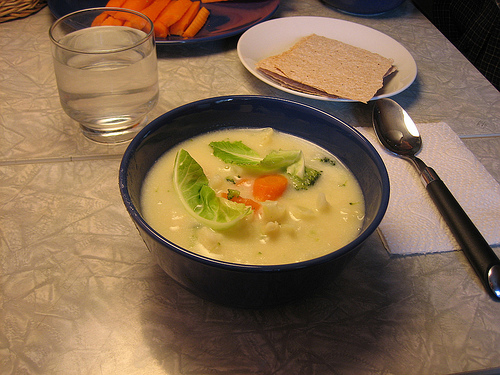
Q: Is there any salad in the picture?
A: No, there is no salad.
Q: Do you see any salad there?
A: No, there is no salad.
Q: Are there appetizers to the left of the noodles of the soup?
A: Yes, there is an appetizer to the left of the noodles.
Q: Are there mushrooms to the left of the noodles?
A: No, there is an appetizer to the left of the noodles.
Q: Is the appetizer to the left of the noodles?
A: Yes, the appetizer is to the left of the noodles.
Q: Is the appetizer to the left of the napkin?
A: Yes, the appetizer is to the left of the napkin.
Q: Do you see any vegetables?
A: Yes, there are vegetables.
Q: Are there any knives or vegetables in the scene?
A: Yes, there are vegetables.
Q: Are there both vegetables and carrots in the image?
A: Yes, there are both vegetables and a carrot.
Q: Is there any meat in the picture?
A: No, there is no meat.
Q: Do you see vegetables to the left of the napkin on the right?
A: Yes, there are vegetables to the left of the napkin.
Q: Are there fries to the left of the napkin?
A: No, there are vegetables to the left of the napkin.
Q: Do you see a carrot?
A: Yes, there are carrots.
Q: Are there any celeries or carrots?
A: Yes, there are carrots.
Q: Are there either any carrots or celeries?
A: Yes, there are carrots.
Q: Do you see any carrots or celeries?
A: Yes, there are carrots.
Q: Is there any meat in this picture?
A: No, there is no meat.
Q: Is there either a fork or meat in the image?
A: No, there are no meat or forks.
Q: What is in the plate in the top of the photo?
A: The carrots are in the plate.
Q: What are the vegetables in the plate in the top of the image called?
A: The vegetables are carrots.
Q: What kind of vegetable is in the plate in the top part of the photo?
A: The vegetables are carrots.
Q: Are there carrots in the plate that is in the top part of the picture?
A: Yes, there are carrots in the plate.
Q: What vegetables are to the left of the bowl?
A: The vegetables are carrots.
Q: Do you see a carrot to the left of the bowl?
A: Yes, there are carrots to the left of the bowl.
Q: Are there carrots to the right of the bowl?
A: No, the carrots are to the left of the bowl.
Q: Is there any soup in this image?
A: Yes, there is soup.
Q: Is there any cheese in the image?
A: No, there is no cheese.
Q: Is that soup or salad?
A: That is soup.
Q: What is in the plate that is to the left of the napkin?
A: The soup is in the plate.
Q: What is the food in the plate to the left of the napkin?
A: The food is soup.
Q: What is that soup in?
A: The soup is in the plate.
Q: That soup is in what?
A: The soup is in the plate.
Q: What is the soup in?
A: The soup is in the plate.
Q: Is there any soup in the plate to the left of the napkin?
A: Yes, there is soup in the plate.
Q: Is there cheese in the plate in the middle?
A: No, there is soup in the plate.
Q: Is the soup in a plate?
A: Yes, the soup is in a plate.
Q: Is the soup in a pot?
A: No, the soup is in a plate.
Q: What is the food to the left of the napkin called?
A: The food is soup.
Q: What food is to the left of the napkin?
A: The food is soup.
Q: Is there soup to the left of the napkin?
A: Yes, there is soup to the left of the napkin.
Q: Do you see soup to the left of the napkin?
A: Yes, there is soup to the left of the napkin.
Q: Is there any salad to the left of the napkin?
A: No, there is soup to the left of the napkin.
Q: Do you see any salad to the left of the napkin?
A: No, there is soup to the left of the napkin.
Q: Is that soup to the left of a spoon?
A: No, the soup is to the left of the napkin.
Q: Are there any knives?
A: No, there are no knives.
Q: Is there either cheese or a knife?
A: No, there are no knives or cheese.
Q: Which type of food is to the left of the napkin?
A: The food is noodles.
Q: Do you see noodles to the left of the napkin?
A: Yes, there are noodles to the left of the napkin.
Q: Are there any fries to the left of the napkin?
A: No, there are noodles to the left of the napkin.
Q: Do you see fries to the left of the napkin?
A: No, there are noodles to the left of the napkin.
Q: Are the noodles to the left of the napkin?
A: Yes, the noodles are to the left of the napkin.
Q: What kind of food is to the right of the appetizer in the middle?
A: The food is noodles.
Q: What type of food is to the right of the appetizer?
A: The food is noodles.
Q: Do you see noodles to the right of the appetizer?
A: Yes, there are noodles to the right of the appetizer.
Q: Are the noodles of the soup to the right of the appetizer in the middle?
A: Yes, the noodles are to the right of the appetizer.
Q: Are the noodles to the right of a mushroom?
A: No, the noodles are to the right of the appetizer.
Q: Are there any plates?
A: Yes, there is a plate.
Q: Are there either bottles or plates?
A: Yes, there is a plate.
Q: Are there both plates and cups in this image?
A: Yes, there are both a plate and a cup.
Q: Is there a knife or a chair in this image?
A: No, there are no knives or chairs.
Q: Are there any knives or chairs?
A: No, there are no knives or chairs.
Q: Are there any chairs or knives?
A: No, there are no knives or chairs.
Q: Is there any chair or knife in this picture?
A: No, there are no knives or chairs.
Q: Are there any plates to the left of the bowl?
A: Yes, there is a plate to the left of the bowl.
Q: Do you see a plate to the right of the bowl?
A: No, the plate is to the left of the bowl.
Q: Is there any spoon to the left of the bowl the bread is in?
A: No, there is a plate to the left of the bowl.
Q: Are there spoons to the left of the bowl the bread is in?
A: No, there is a plate to the left of the bowl.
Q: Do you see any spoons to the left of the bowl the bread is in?
A: No, there is a plate to the left of the bowl.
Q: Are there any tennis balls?
A: No, there are no tennis balls.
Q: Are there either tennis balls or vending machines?
A: No, there are no tennis balls or vending machines.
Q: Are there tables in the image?
A: Yes, there is a table.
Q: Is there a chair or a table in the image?
A: Yes, there is a table.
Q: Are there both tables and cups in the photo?
A: Yes, there are both a table and a cup.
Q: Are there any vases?
A: No, there are no vases.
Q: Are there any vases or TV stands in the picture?
A: No, there are no vases or TV stands.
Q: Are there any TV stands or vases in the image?
A: No, there are no vases or TV stands.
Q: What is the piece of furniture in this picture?
A: The piece of furniture is a table.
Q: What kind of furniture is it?
A: The piece of furniture is a table.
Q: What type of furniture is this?
A: This is a table.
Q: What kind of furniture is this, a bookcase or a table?
A: This is a table.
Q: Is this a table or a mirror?
A: This is a table.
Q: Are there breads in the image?
A: Yes, there is a bread.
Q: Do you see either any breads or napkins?
A: Yes, there is a bread.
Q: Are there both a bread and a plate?
A: Yes, there are both a bread and a plate.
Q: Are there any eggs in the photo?
A: No, there are no eggs.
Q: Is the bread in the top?
A: Yes, the bread is in the top of the image.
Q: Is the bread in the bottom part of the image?
A: No, the bread is in the top of the image.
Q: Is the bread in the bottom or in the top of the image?
A: The bread is in the top of the image.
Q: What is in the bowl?
A: The bread is in the bowl.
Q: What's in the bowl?
A: The bread is in the bowl.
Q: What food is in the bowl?
A: The food is a bread.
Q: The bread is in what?
A: The bread is in the bowl.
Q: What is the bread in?
A: The bread is in the bowl.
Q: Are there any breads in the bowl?
A: Yes, there is a bread in the bowl.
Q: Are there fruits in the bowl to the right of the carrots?
A: No, there is a bread in the bowl.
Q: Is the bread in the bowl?
A: Yes, the bread is in the bowl.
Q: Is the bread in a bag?
A: No, the bread is in the bowl.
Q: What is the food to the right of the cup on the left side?
A: The food is a bread.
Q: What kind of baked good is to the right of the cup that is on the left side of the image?
A: The food is a bread.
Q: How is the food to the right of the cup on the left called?
A: The food is a bread.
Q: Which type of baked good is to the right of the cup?
A: The food is a bread.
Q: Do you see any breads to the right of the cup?
A: Yes, there is a bread to the right of the cup.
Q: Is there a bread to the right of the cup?
A: Yes, there is a bread to the right of the cup.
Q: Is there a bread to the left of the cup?
A: No, the bread is to the right of the cup.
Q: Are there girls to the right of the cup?
A: No, there is a bread to the right of the cup.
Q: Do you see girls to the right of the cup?
A: No, there is a bread to the right of the cup.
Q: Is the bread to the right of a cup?
A: Yes, the bread is to the right of a cup.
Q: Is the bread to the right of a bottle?
A: No, the bread is to the right of a cup.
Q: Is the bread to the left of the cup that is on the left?
A: No, the bread is to the right of the cup.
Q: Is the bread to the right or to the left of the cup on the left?
A: The bread is to the right of the cup.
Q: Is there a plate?
A: Yes, there is a plate.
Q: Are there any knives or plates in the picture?
A: Yes, there is a plate.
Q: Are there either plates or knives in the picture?
A: Yes, there is a plate.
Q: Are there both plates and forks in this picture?
A: No, there is a plate but no forks.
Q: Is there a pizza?
A: No, there are no pizzas.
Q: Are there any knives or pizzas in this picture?
A: No, there are no pizzas or knives.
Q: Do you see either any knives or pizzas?
A: No, there are no pizzas or knives.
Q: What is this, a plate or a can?
A: This is a plate.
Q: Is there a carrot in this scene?
A: Yes, there are carrots.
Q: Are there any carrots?
A: Yes, there are carrots.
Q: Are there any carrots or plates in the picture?
A: Yes, there are carrots.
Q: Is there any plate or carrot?
A: Yes, there are carrots.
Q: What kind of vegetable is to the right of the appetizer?
A: The vegetables are carrots.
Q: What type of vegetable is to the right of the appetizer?
A: The vegetables are carrots.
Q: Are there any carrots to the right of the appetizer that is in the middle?
A: Yes, there are carrots to the right of the appetizer.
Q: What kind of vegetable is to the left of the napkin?
A: The vegetables are carrots.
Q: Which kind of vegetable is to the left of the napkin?
A: The vegetables are carrots.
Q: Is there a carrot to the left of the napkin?
A: Yes, there are carrots to the left of the napkin.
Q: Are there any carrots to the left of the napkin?
A: Yes, there are carrots to the left of the napkin.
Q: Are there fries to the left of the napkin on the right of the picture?
A: No, there are carrots to the left of the napkin.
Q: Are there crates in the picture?
A: No, there are no crates.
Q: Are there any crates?
A: No, there are no crates.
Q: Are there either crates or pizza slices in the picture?
A: No, there are no crates or pizza slices.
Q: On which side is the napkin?
A: The napkin is on the right of the image.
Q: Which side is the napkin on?
A: The napkin is on the right of the image.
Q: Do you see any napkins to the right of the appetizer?
A: Yes, there is a napkin to the right of the appetizer.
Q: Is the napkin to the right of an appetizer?
A: Yes, the napkin is to the right of an appetizer.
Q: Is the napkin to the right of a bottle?
A: No, the napkin is to the right of an appetizer.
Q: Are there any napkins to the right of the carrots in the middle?
A: Yes, there is a napkin to the right of the carrots.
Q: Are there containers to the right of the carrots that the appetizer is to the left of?
A: No, there is a napkin to the right of the carrots.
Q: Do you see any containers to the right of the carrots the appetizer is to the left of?
A: No, there is a napkin to the right of the carrots.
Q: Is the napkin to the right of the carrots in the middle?
A: Yes, the napkin is to the right of the carrots.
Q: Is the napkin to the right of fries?
A: No, the napkin is to the right of the carrots.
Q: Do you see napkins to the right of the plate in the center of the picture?
A: Yes, there is a napkin to the right of the plate.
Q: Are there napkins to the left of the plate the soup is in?
A: No, the napkin is to the right of the plate.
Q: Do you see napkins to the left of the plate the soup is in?
A: No, the napkin is to the right of the plate.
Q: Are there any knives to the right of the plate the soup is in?
A: No, there is a napkin to the right of the plate.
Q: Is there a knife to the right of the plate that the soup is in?
A: No, there is a napkin to the right of the plate.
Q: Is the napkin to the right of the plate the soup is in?
A: Yes, the napkin is to the right of the plate.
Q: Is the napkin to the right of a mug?
A: No, the napkin is to the right of the plate.